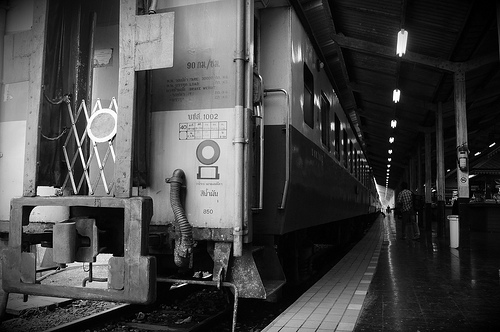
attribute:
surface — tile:
[269, 179, 407, 329]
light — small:
[384, 84, 413, 109]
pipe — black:
[162, 161, 204, 257]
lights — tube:
[379, 20, 411, 206]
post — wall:
[452, 70, 469, 197]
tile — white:
[349, 302, 362, 312]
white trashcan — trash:
[446, 212, 462, 252]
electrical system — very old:
[142, 102, 256, 269]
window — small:
[291, 91, 369, 148]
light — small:
[385, 145, 394, 155]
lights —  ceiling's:
[371, 28, 428, 215]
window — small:
[298, 61, 329, 137]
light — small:
[387, 149, 393, 156]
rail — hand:
[255, 86, 290, 209]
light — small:
[387, 148, 395, 155]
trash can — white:
[448, 215, 460, 250]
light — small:
[381, 85, 403, 106]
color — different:
[293, 199, 379, 319]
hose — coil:
[157, 160, 202, 266]